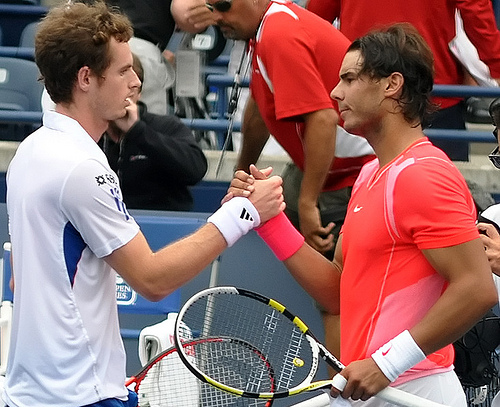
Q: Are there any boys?
A: No, there are no boys.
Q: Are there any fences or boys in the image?
A: No, there are no boys or fences.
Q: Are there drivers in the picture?
A: No, there are no drivers.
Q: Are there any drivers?
A: No, there are no drivers.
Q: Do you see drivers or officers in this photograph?
A: No, there are no drivers or officers.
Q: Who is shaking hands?
A: The man is shaking hands.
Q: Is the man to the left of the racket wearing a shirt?
A: Yes, the man is wearing a shirt.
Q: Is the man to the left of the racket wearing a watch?
A: No, the man is wearing a shirt.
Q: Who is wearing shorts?
A: The man is wearing shorts.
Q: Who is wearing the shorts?
A: The man is wearing shorts.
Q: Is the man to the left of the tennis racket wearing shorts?
A: Yes, the man is wearing shorts.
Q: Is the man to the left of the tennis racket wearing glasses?
A: No, the man is wearing shorts.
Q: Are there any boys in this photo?
A: No, there are no boys.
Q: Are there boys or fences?
A: No, there are no boys or fences.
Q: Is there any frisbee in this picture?
A: No, there are no frisbees.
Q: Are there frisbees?
A: No, there are no frisbees.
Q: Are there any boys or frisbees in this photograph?
A: No, there are no frisbees or boys.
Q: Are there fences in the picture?
A: No, there are no fences.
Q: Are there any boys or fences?
A: No, there are no fences or boys.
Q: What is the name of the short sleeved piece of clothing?
A: The clothing item is a shirt.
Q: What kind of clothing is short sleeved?
A: The clothing is a shirt.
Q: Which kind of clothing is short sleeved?
A: The clothing is a shirt.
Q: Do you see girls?
A: No, there are no girls.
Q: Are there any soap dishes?
A: No, there are no soap dishes.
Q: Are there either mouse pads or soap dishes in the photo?
A: No, there are no soap dishes or mouse pads.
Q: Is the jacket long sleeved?
A: Yes, the jacket is long sleeved.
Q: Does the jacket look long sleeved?
A: Yes, the jacket is long sleeved.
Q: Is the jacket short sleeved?
A: No, the jacket is long sleeved.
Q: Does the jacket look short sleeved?
A: No, the jacket is long sleeved.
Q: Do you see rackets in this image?
A: Yes, there is a racket.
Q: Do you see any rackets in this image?
A: Yes, there is a racket.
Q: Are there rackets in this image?
A: Yes, there is a racket.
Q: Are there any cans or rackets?
A: Yes, there is a racket.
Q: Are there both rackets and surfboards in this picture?
A: No, there is a racket but no surfboards.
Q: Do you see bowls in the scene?
A: No, there are no bowls.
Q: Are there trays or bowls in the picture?
A: No, there are no bowls or trays.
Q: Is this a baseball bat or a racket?
A: This is a racket.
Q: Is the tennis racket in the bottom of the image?
A: Yes, the tennis racket is in the bottom of the image.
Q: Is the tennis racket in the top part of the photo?
A: No, the tennis racket is in the bottom of the image.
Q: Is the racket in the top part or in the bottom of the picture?
A: The racket is in the bottom of the image.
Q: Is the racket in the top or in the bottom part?
A: The racket is in the bottom of the image.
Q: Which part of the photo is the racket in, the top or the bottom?
A: The racket is in the bottom of the image.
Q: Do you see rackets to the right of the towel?
A: Yes, there is a racket to the right of the towel.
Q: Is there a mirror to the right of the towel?
A: No, there is a racket to the right of the towel.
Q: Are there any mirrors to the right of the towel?
A: No, there is a racket to the right of the towel.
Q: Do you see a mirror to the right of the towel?
A: No, there is a racket to the right of the towel.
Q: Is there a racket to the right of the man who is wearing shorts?
A: Yes, there is a racket to the right of the man.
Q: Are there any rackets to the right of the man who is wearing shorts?
A: Yes, there is a racket to the right of the man.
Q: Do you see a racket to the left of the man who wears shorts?
A: No, the racket is to the right of the man.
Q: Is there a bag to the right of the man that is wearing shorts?
A: No, there is a racket to the right of the man.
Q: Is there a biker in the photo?
A: No, there are no bikers.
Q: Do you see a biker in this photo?
A: No, there are no bikers.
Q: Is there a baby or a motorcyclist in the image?
A: No, there are no bikers or babies.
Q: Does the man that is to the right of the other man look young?
A: Yes, the man is young.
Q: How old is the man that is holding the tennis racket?
A: The man is young.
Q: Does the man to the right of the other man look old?
A: No, the man is young.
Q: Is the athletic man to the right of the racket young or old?
A: The man is young.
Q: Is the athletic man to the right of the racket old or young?
A: The man is young.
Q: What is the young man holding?
A: The man is holding the tennis racket.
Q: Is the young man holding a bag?
A: No, the man is holding the tennis racket.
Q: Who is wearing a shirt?
A: The man is wearing a shirt.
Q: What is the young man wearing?
A: The man is wearing a shirt.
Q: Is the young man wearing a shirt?
A: Yes, the man is wearing a shirt.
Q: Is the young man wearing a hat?
A: No, the man is wearing a shirt.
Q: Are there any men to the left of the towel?
A: No, the man is to the right of the towel.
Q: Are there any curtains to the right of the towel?
A: No, there is a man to the right of the towel.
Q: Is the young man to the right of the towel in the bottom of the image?
A: Yes, the man is to the right of the towel.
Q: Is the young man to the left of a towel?
A: No, the man is to the right of a towel.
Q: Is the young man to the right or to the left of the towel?
A: The man is to the right of the towel.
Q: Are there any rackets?
A: Yes, there is a racket.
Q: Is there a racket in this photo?
A: Yes, there is a racket.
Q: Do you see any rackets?
A: Yes, there is a racket.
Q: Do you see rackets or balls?
A: Yes, there is a racket.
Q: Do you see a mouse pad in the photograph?
A: No, there are no mouse pads.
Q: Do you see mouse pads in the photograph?
A: No, there are no mouse pads.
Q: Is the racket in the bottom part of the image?
A: Yes, the racket is in the bottom of the image.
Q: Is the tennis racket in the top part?
A: No, the tennis racket is in the bottom of the image.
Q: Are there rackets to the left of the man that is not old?
A: Yes, there is a racket to the left of the man.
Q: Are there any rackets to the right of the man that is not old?
A: No, the racket is to the left of the man.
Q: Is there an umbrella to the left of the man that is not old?
A: No, there is a racket to the left of the man.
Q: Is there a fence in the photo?
A: No, there are no fences.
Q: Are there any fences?
A: No, there are no fences.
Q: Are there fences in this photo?
A: No, there are no fences.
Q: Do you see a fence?
A: No, there are no fences.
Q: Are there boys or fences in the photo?
A: No, there are no fences or boys.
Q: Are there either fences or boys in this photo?
A: No, there are no fences or boys.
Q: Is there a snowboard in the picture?
A: No, there are no snowboards.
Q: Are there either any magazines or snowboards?
A: No, there are no snowboards or magazines.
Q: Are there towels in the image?
A: Yes, there is a towel.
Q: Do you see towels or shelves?
A: Yes, there is a towel.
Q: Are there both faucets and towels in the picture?
A: No, there is a towel but no faucets.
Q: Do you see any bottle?
A: No, there are no bottles.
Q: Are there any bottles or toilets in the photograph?
A: No, there are no bottles or toilets.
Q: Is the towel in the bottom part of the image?
A: Yes, the towel is in the bottom of the image.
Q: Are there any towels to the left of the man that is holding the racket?
A: Yes, there is a towel to the left of the man.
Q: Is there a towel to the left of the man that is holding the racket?
A: Yes, there is a towel to the left of the man.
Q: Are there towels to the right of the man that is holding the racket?
A: No, the towel is to the left of the man.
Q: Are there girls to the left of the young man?
A: No, there is a towel to the left of the man.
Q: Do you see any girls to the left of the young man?
A: No, there is a towel to the left of the man.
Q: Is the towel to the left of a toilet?
A: No, the towel is to the left of the man.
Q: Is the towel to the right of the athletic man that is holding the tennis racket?
A: No, the towel is to the left of the man.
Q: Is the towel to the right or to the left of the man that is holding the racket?
A: The towel is to the left of the man.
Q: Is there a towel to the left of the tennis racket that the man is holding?
A: Yes, there is a towel to the left of the tennis racket.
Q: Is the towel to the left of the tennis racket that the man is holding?
A: Yes, the towel is to the left of the racket.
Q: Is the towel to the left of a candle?
A: No, the towel is to the left of the racket.